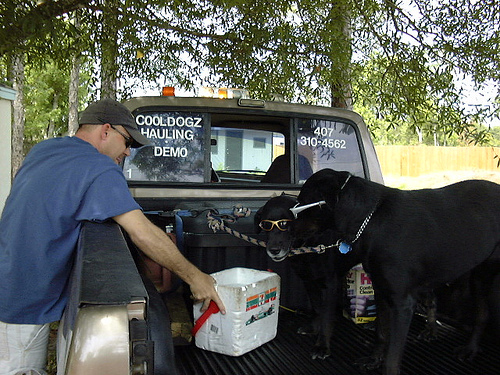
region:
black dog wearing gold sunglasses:
[254, 195, 332, 361]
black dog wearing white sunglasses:
[291, 169, 498, 373]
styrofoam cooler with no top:
[194, 262, 281, 357]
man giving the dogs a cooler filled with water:
[0, 98, 225, 361]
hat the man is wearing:
[74, 95, 151, 150]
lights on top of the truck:
[156, 84, 251, 99]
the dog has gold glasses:
[254, 197, 338, 359]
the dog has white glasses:
[297, 170, 497, 365]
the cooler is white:
[194, 268, 279, 355]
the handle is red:
[182, 303, 220, 333]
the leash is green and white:
[210, 215, 339, 255]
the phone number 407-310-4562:
[301, 125, 346, 149]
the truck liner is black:
[129, 193, 478, 370]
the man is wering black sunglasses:
[6, 99, 227, 371]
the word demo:
[153, 145, 188, 158]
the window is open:
[208, 113, 295, 187]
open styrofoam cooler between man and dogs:
[5, 95, 492, 370]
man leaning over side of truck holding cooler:
[6, 97, 231, 368]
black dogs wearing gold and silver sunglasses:
[247, 162, 488, 362]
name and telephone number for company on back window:
[132, 110, 350, 164]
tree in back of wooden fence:
[352, 52, 499, 181]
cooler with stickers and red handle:
[190, 256, 280, 356]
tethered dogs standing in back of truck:
[126, 171, 491, 368]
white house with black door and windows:
[207, 123, 275, 176]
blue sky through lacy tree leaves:
[6, 4, 497, 149]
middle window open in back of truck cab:
[126, 110, 370, 195]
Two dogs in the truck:
[251, 152, 416, 289]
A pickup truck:
[140, 75, 336, 341]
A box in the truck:
[197, 266, 277, 367]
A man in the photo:
[7, 96, 152, 363]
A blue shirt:
[19, 149, 93, 297]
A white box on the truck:
[200, 254, 276, 354]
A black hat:
[82, 93, 162, 144]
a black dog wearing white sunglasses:
[294, 166, 498, 373]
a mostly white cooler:
[186, 263, 281, 363]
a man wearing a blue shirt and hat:
[3, 98, 229, 374]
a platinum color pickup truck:
[58, 95, 395, 372]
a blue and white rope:
[207, 198, 339, 264]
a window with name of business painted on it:
[126, 110, 211, 183]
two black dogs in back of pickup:
[52, 85, 498, 373]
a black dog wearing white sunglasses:
[287, 166, 497, 373]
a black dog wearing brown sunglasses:
[249, 191, 363, 363]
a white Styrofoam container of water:
[188, 261, 280, 358]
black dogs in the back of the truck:
[252, 158, 498, 373]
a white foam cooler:
[190, 266, 282, 355]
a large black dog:
[295, 168, 497, 373]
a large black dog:
[247, 195, 360, 360]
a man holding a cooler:
[0, 100, 283, 372]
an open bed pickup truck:
[53, 85, 498, 373]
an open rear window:
[208, 116, 291, 183]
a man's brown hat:
[78, 100, 155, 150]